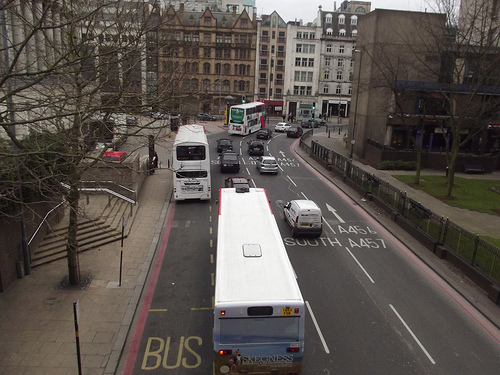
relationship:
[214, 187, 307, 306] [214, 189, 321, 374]
roof of bus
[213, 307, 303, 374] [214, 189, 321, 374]
back of bus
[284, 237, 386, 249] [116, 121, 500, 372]
street name on street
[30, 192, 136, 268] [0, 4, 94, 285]
steps in front of building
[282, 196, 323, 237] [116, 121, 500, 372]
van on street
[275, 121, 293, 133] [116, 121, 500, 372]
car on street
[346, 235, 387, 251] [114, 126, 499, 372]
numbers on road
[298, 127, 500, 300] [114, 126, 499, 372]
fence beside road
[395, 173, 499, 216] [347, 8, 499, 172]
grass in front of building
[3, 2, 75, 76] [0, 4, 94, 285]
pillars on building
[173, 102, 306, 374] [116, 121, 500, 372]
busses on street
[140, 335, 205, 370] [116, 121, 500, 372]
bus written on street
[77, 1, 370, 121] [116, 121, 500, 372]
buildings are beyond street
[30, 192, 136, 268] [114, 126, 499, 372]
steps by road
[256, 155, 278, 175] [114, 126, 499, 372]
car on road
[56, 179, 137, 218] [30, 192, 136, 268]
handrail by steps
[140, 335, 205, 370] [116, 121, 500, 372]
bus printed on street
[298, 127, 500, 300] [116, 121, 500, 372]
fence by street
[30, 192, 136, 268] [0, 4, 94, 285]
steps leading to building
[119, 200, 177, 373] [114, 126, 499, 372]
stripe alongside road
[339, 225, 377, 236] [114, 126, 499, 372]
a456 written on road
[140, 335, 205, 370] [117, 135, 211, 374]
bus printed on street lane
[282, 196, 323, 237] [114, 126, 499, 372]
van on road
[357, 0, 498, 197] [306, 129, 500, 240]
trees near sidewalk